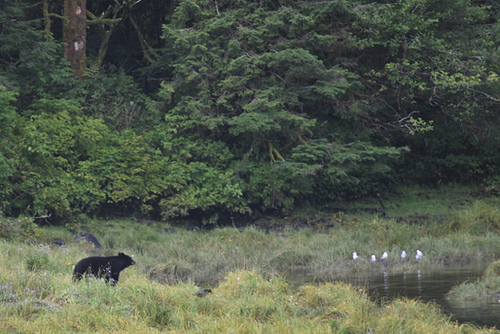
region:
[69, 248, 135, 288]
black bear in a field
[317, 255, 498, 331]
body of water in the field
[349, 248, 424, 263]
ducks on the edge of the water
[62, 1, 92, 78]
tree with some bark missing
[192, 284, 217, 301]
bird looking in the tall grass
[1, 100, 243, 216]
green leafy tree at edge of woods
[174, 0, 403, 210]
evergreen tree near the edge of woods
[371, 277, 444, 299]
ripples in the water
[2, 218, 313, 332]
field of overgrown grass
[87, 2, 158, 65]
dead trees in the woods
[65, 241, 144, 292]
Bear looks at birds.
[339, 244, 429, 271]
Birds near a lake.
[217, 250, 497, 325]
A lake in middle of field.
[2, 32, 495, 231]
Trees surround the field.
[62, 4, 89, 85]
Large brown tree trunk.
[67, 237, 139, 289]
Black bear stands in grass.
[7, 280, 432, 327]
Wild grass litters field.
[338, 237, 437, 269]
A flock of birds stand in grass.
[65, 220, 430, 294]
Black bear watches group of white birds.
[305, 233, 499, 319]
Flock of white birds near lake.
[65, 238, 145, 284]
black bear in forest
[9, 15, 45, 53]
green leaves on brown trees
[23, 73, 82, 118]
green leaves on brown trees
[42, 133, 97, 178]
green leaves on brown trees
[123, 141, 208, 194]
green leaves on brown trees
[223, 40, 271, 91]
green leaves on brown trees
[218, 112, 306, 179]
green leaves on brown trees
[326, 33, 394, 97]
green leaves on brown trees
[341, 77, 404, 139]
green leaves on brown trees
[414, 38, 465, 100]
green leaves on brown trees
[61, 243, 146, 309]
the bear is black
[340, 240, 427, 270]
the birds are white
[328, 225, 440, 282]
the birds are white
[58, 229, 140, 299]
black bear in tall grass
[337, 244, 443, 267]
row of white birds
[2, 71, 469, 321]
forest scene with bear and birds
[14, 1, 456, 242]
heavy trees in a forest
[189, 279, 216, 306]
gray bird in tall grass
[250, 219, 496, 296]
creek with birds alongside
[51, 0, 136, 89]
bare tree in forest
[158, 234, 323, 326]
forest grass during summer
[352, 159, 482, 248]
forest grass during daytime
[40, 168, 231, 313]
bird and bear in forest